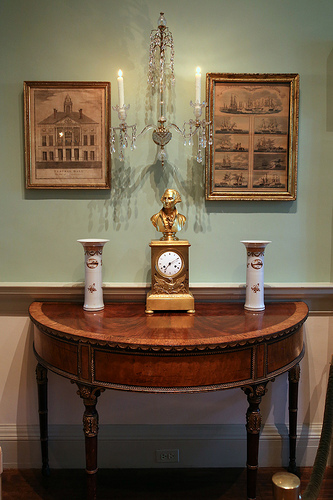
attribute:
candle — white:
[117, 70, 126, 106]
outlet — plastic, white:
[154, 448, 179, 463]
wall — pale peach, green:
[2, 0, 331, 468]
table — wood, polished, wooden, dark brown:
[29, 299, 311, 491]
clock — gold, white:
[147, 239, 196, 314]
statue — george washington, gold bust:
[151, 188, 189, 240]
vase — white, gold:
[241, 239, 272, 312]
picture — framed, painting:
[205, 71, 298, 205]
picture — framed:
[21, 80, 111, 191]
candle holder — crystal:
[110, 104, 139, 152]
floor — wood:
[0, 468, 333, 498]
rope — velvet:
[308, 360, 333, 500]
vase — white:
[78, 237, 110, 311]